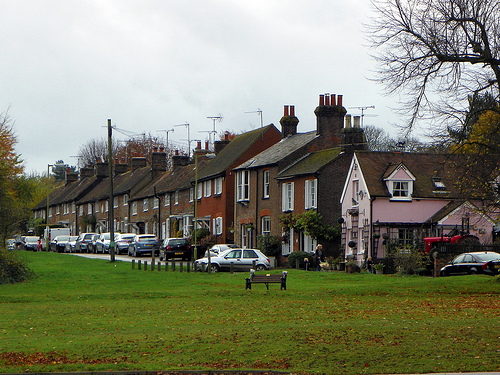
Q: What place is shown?
A: It is a field.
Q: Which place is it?
A: It is a field.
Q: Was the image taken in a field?
A: Yes, it was taken in a field.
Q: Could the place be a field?
A: Yes, it is a field.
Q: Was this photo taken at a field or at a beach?
A: It was taken at a field.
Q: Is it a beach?
A: No, it is a field.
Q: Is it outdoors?
A: Yes, it is outdoors.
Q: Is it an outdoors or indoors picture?
A: It is outdoors.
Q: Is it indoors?
A: No, it is outdoors.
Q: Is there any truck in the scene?
A: No, there are no trucks.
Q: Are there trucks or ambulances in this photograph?
A: No, there are no trucks or ambulances.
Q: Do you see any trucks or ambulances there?
A: No, there are no trucks or ambulances.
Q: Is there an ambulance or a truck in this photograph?
A: No, there are no trucks or ambulances.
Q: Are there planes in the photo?
A: No, there are no planes.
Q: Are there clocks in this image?
A: No, there are no clocks.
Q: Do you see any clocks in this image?
A: No, there are no clocks.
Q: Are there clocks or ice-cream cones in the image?
A: No, there are no clocks or ice-cream cones.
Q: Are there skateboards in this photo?
A: No, there are no skateboards.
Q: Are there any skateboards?
A: No, there are no skateboards.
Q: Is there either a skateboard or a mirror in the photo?
A: No, there are no skateboards or mirrors.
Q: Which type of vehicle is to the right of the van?
A: The vehicle is a car.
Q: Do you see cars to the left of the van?
A: No, the car is to the right of the van.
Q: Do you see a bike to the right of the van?
A: No, there is a car to the right of the van.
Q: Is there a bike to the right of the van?
A: No, there is a car to the right of the van.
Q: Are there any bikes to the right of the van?
A: No, there is a car to the right of the van.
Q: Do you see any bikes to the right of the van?
A: No, there is a car to the right of the van.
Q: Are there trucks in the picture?
A: No, there are no trucks.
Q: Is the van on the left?
A: Yes, the van is on the left of the image.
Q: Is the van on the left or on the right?
A: The van is on the left of the image.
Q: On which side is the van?
A: The van is on the left of the image.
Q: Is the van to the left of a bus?
A: No, the van is to the left of a car.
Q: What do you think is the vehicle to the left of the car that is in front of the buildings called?
A: The vehicle is a van.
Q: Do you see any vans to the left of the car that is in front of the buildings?
A: Yes, there is a van to the left of the car.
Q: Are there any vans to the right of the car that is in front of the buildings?
A: No, the van is to the left of the car.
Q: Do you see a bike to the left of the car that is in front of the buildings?
A: No, there is a van to the left of the car.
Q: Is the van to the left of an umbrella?
A: No, the van is to the left of the car.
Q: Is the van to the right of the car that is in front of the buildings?
A: No, the van is to the left of the car.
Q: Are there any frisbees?
A: No, there are no frisbees.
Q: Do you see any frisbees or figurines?
A: No, there are no frisbees or figurines.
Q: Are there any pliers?
A: No, there are no pliers.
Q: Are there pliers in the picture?
A: No, there are no pliers.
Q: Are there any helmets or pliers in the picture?
A: No, there are no pliers or helmets.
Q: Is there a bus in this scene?
A: No, there are no buses.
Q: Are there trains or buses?
A: No, there are no buses or trains.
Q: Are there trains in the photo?
A: No, there are no trains.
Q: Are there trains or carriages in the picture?
A: No, there are no trains or carriages.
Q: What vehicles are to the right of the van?
A: The vehicles are cars.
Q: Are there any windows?
A: Yes, there is a window.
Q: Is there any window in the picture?
A: Yes, there is a window.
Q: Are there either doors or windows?
A: Yes, there is a window.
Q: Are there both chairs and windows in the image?
A: No, there is a window but no chairs.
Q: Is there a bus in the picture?
A: No, there are no buses.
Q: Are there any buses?
A: No, there are no buses.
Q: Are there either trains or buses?
A: No, there are no buses or trains.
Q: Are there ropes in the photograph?
A: No, there are no ropes.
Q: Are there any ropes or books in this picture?
A: No, there are no ropes or books.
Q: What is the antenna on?
A: The antenna is on the building.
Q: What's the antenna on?
A: The antenna is on the building.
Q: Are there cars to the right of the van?
A: Yes, there are cars to the right of the van.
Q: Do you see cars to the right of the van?
A: Yes, there are cars to the right of the van.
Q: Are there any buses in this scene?
A: No, there are no buses.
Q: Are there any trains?
A: No, there are no trains.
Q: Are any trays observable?
A: No, there are no trays.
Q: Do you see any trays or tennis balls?
A: No, there are no trays or tennis balls.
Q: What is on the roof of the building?
A: The chimney is on the roof.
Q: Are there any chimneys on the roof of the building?
A: Yes, there is a chimney on the roof.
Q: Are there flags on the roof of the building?
A: No, there is a chimney on the roof.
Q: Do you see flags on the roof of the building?
A: No, there is a chimney on the roof.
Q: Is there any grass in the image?
A: Yes, there is grass.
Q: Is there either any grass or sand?
A: Yes, there is grass.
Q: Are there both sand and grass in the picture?
A: No, there is grass but no sand.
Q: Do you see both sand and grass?
A: No, there is grass but no sand.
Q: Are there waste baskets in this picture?
A: No, there are no waste baskets.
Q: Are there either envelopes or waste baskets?
A: No, there are no waste baskets or envelopes.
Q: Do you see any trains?
A: No, there are no trains.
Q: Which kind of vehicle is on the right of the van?
A: The vehicle is a car.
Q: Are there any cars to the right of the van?
A: Yes, there is a car to the right of the van.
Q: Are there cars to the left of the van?
A: No, the car is to the right of the van.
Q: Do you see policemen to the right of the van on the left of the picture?
A: No, there is a car to the right of the van.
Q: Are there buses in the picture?
A: No, there are no buses.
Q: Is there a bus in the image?
A: No, there are no buses.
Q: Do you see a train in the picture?
A: No, there are no trains.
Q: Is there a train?
A: No, there are no trains.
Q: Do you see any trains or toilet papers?
A: No, there are no trains or toilet papers.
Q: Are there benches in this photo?
A: Yes, there is a bench.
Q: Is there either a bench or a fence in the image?
A: Yes, there is a bench.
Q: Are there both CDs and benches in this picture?
A: No, there is a bench but no cds.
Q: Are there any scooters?
A: No, there are no scooters.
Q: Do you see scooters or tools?
A: No, there are no scooters or tools.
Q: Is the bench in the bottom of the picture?
A: Yes, the bench is in the bottom of the image.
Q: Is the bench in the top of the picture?
A: No, the bench is in the bottom of the image.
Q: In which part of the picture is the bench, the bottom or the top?
A: The bench is in the bottom of the image.